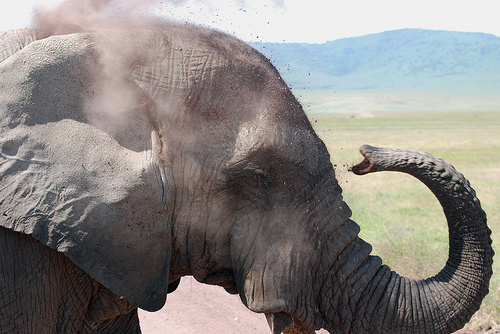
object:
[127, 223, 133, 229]
mark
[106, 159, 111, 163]
mark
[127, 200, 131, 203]
mark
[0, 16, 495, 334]
elephant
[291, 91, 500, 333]
field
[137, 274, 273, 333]
road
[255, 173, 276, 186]
right eye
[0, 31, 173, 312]
ear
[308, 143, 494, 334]
trunk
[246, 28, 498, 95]
mountain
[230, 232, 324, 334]
mouth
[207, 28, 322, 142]
forehead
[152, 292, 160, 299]
spot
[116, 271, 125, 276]
spot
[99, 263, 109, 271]
spot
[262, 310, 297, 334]
tush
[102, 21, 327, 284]
head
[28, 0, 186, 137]
dust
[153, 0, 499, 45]
sky